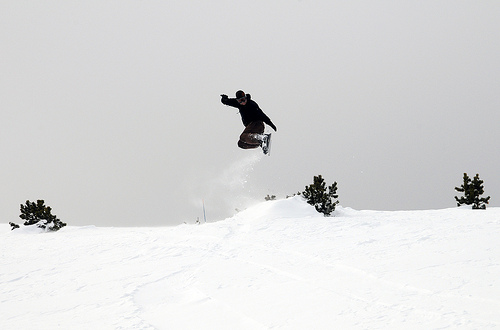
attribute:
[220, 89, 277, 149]
man — flying, airborne, jumping, gliding, snowboarding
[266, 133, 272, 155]
board — black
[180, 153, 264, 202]
snow — white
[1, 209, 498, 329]
hill — covered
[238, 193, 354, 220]
snow — piled, white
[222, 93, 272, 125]
jacket — black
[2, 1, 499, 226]
sky — white, bright, cloudy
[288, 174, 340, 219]
bush — green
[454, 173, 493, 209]
bush — green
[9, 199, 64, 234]
bush — green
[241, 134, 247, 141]
knee — bent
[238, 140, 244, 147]
knee — bent